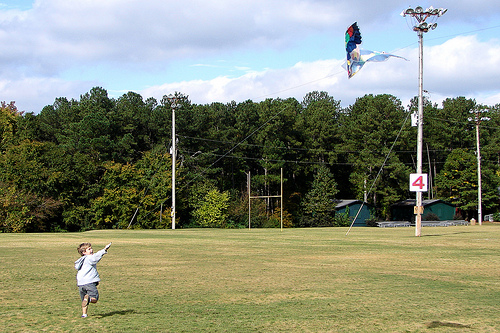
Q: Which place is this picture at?
A: It is at the field.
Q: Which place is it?
A: It is a field.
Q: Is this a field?
A: Yes, it is a field.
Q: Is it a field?
A: Yes, it is a field.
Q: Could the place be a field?
A: Yes, it is a field.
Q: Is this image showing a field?
A: Yes, it is showing a field.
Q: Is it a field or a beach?
A: It is a field.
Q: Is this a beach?
A: No, it is a field.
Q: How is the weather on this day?
A: It is clear.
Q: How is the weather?
A: It is clear.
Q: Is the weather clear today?
A: Yes, it is clear.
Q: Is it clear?
A: Yes, it is clear.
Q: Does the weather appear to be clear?
A: Yes, it is clear.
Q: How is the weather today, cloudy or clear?
A: It is clear.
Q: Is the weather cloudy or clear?
A: It is clear.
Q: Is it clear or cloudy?
A: It is clear.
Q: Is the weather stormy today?
A: No, it is clear.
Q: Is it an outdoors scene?
A: Yes, it is outdoors.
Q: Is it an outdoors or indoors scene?
A: It is outdoors.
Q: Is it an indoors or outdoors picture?
A: It is outdoors.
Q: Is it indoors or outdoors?
A: It is outdoors.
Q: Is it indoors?
A: No, it is outdoors.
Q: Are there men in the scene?
A: No, there are no men.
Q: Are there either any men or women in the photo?
A: No, there are no men or women.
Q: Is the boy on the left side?
A: Yes, the boy is on the left of the image.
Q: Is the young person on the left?
A: Yes, the boy is on the left of the image.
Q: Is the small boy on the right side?
A: No, the boy is on the left of the image.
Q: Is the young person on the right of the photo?
A: No, the boy is on the left of the image.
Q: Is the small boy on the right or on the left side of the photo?
A: The boy is on the left of the image.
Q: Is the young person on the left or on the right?
A: The boy is on the left of the image.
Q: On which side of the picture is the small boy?
A: The boy is on the left of the image.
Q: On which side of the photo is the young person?
A: The boy is on the left of the image.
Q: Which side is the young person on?
A: The boy is on the left of the image.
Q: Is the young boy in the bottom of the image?
A: Yes, the boy is in the bottom of the image.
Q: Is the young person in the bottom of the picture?
A: Yes, the boy is in the bottom of the image.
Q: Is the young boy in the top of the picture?
A: No, the boy is in the bottom of the image.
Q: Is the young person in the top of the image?
A: No, the boy is in the bottom of the image.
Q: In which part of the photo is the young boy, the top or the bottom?
A: The boy is in the bottom of the image.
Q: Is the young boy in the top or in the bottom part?
A: The boy is in the bottom of the image.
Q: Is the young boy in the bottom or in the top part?
A: The boy is in the bottom of the image.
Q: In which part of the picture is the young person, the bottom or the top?
A: The boy is in the bottom of the image.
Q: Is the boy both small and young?
A: Yes, the boy is small and young.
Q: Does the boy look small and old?
A: No, the boy is small but young.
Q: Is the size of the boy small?
A: Yes, the boy is small.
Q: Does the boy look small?
A: Yes, the boy is small.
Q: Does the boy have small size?
A: Yes, the boy is small.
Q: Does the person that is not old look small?
A: Yes, the boy is small.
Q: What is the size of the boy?
A: The boy is small.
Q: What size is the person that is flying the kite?
A: The boy is small.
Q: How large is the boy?
A: The boy is small.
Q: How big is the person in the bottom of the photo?
A: The boy is small.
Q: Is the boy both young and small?
A: Yes, the boy is young and small.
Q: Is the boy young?
A: Yes, the boy is young.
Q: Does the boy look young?
A: Yes, the boy is young.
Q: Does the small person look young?
A: Yes, the boy is young.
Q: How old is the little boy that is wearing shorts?
A: The boy is young.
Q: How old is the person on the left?
A: The boy is young.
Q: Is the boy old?
A: No, the boy is young.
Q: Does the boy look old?
A: No, the boy is young.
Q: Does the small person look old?
A: No, the boy is young.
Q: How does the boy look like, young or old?
A: The boy is young.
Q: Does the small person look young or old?
A: The boy is young.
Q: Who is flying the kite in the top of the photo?
A: The boy is flying the kite.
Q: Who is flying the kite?
A: The boy is flying the kite.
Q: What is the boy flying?
A: The boy is flying the kite.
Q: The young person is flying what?
A: The boy is flying the kite.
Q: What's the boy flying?
A: The boy is flying the kite.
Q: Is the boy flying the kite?
A: Yes, the boy is flying the kite.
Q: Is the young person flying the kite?
A: Yes, the boy is flying the kite.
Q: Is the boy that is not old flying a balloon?
A: No, the boy is flying the kite.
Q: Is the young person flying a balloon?
A: No, the boy is flying the kite.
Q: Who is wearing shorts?
A: The boy is wearing shorts.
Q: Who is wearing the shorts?
A: The boy is wearing shorts.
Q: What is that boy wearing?
A: The boy is wearing shorts.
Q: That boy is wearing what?
A: The boy is wearing shorts.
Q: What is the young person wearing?
A: The boy is wearing shorts.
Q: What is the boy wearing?
A: The boy is wearing shorts.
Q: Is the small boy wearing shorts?
A: Yes, the boy is wearing shorts.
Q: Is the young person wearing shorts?
A: Yes, the boy is wearing shorts.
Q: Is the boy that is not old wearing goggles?
A: No, the boy is wearing shorts.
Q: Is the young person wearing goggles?
A: No, the boy is wearing shorts.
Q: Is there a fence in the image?
A: No, there are no fences.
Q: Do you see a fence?
A: No, there are no fences.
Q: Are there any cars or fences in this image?
A: No, there are no fences or cars.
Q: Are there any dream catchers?
A: No, there are no dream catchers.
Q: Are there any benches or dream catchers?
A: No, there are no dream catchers or benches.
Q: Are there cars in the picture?
A: No, there are no cars.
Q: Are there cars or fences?
A: No, there are no cars or fences.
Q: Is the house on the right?
A: Yes, the house is on the right of the image.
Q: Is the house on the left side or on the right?
A: The house is on the right of the image.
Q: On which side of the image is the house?
A: The house is on the right of the image.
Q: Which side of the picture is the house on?
A: The house is on the right of the image.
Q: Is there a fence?
A: No, there are no fences.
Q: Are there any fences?
A: No, there are no fences.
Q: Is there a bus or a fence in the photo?
A: No, there are no fences or buses.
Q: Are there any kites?
A: Yes, there is a kite.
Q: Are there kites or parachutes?
A: Yes, there is a kite.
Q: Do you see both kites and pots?
A: No, there is a kite but no pots.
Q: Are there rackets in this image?
A: No, there are no rackets.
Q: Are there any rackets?
A: No, there are no rackets.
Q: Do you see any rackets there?
A: No, there are no rackets.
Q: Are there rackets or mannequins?
A: No, there are no rackets or mannequins.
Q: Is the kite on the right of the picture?
A: Yes, the kite is on the right of the image.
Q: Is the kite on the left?
A: No, the kite is on the right of the image.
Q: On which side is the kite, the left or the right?
A: The kite is on the right of the image.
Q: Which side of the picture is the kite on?
A: The kite is on the right of the image.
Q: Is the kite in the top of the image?
A: Yes, the kite is in the top of the image.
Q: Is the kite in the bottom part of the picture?
A: No, the kite is in the top of the image.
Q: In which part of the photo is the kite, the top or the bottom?
A: The kite is in the top of the image.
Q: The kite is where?
A: The kite is in the sky.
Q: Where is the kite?
A: The kite is in the sky.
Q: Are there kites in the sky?
A: Yes, there is a kite in the sky.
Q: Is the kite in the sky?
A: Yes, the kite is in the sky.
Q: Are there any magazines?
A: No, there are no magazines.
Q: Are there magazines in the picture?
A: No, there are no magazines.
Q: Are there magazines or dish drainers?
A: No, there are no magazines or dish drainers.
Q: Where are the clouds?
A: The clouds are in the sky.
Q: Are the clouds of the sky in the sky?
A: Yes, the clouds are in the sky.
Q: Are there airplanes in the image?
A: No, there are no airplanes.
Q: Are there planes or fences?
A: No, there are no planes or fences.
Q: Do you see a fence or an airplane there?
A: No, there are no airplanes or fences.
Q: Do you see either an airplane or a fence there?
A: No, there are no airplanes or fences.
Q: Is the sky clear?
A: Yes, the sky is clear.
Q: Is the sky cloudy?
A: No, the sky is clear.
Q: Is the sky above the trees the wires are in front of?
A: Yes, the sky is above the trees.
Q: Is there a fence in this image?
A: No, there are no fences.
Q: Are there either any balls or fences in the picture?
A: No, there are no fences or balls.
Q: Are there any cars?
A: No, there are no cars.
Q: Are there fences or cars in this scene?
A: No, there are no cars or fences.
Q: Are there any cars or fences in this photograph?
A: No, there are no cars or fences.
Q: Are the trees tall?
A: Yes, the trees are tall.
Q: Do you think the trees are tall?
A: Yes, the trees are tall.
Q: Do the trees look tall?
A: Yes, the trees are tall.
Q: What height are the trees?
A: The trees are tall.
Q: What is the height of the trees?
A: The trees are tall.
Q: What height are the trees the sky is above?
A: The trees are tall.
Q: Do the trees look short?
A: No, the trees are tall.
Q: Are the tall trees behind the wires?
A: Yes, the trees are behind the wires.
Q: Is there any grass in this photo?
A: Yes, there is grass.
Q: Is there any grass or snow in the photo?
A: Yes, there is grass.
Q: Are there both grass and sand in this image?
A: No, there is grass but no sand.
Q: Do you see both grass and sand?
A: No, there is grass but no sand.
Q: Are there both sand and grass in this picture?
A: No, there is grass but no sand.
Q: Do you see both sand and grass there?
A: No, there is grass but no sand.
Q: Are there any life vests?
A: No, there are no life vests.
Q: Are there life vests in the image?
A: No, there are no life vests.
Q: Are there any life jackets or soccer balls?
A: No, there are no life jackets or soccer balls.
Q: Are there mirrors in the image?
A: No, there are no mirrors.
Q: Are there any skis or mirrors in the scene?
A: No, there are no mirrors or skis.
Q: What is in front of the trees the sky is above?
A: The wires are in front of the trees.